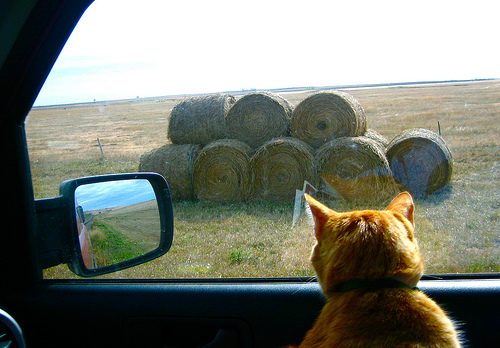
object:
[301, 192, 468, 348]
cat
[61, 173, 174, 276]
mirror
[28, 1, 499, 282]
window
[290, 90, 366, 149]
bale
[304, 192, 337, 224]
ear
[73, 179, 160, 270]
reflection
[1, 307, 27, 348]
vent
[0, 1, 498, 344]
car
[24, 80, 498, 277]
field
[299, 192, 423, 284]
head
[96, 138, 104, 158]
fence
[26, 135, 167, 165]
post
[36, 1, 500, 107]
sky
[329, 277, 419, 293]
collar